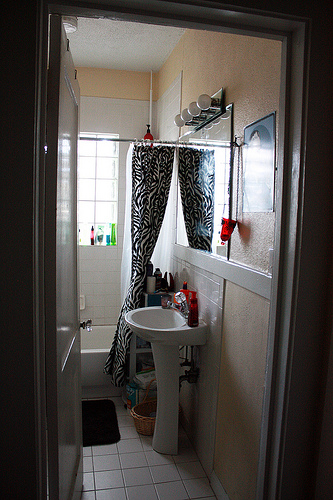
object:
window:
[76, 133, 118, 242]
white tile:
[182, 478, 210, 495]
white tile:
[175, 461, 206, 480]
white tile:
[154, 481, 186, 495]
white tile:
[123, 482, 155, 497]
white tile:
[97, 488, 125, 497]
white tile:
[151, 463, 179, 482]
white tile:
[123, 466, 152, 486]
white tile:
[94, 469, 122, 488]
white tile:
[83, 471, 96, 488]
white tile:
[144, 448, 170, 464]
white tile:
[119, 452, 146, 469]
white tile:
[91, 453, 121, 468]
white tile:
[141, 435, 152, 451]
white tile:
[120, 438, 140, 456]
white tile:
[92, 440, 116, 455]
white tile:
[117, 427, 137, 437]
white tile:
[118, 415, 132, 426]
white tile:
[115, 401, 131, 415]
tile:
[93, 470, 126, 489]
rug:
[80, 398, 121, 447]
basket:
[130, 380, 183, 436]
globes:
[196, 93, 211, 110]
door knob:
[80, 318, 93, 333]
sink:
[131, 309, 184, 332]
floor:
[81, 441, 222, 498]